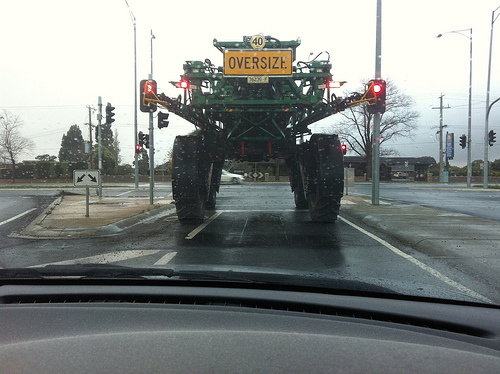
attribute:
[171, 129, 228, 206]
wheel — rear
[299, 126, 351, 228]
tire — big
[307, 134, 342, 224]
tire — black, large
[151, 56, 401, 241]
car — white 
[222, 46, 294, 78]
sign — yellow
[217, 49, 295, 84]
sign — large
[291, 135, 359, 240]
tire — large, black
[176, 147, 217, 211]
tire — black, large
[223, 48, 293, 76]
sign — yellow, black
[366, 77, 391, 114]
traffic signals — red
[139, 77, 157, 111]
traffic signals — red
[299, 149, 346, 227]
wheel — rear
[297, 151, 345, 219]
wheel — back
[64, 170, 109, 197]
arrows — black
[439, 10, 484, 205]
light — tall, street